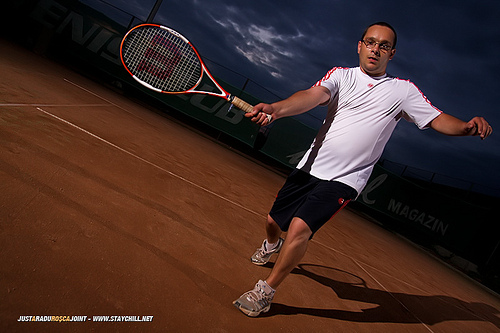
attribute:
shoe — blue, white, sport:
[248, 236, 280, 265]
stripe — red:
[317, 61, 340, 85]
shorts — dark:
[262, 162, 351, 237]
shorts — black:
[269, 165, 360, 246]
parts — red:
[338, 198, 347, 208]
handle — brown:
[229, 97, 280, 123]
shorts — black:
[266, 167, 356, 241]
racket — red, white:
[92, 13, 262, 114]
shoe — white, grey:
[224, 273, 294, 326]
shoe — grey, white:
[245, 230, 300, 270]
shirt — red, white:
[314, 63, 426, 196]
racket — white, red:
[95, 17, 230, 109]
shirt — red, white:
[297, 70, 461, 200]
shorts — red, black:
[249, 148, 370, 261]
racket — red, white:
[100, 9, 276, 158]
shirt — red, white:
[312, 71, 466, 204]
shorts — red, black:
[274, 159, 379, 245]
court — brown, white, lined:
[21, 96, 390, 305]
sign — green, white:
[73, 16, 297, 130]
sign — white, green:
[360, 160, 480, 250]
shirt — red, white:
[287, 66, 445, 231]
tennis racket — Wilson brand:
[117, 18, 274, 122]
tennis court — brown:
[0, 48, 499, 331]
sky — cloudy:
[102, 0, 499, 192]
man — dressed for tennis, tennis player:
[231, 18, 494, 318]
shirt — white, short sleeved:
[297, 65, 442, 200]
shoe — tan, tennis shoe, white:
[232, 277, 274, 318]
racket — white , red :
[115, 17, 275, 131]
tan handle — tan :
[228, 87, 282, 136]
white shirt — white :
[262, 62, 460, 199]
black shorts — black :
[235, 155, 395, 251]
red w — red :
[142, 30, 196, 97]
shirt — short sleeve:
[273, 54, 453, 202]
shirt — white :
[297, 65, 454, 204]